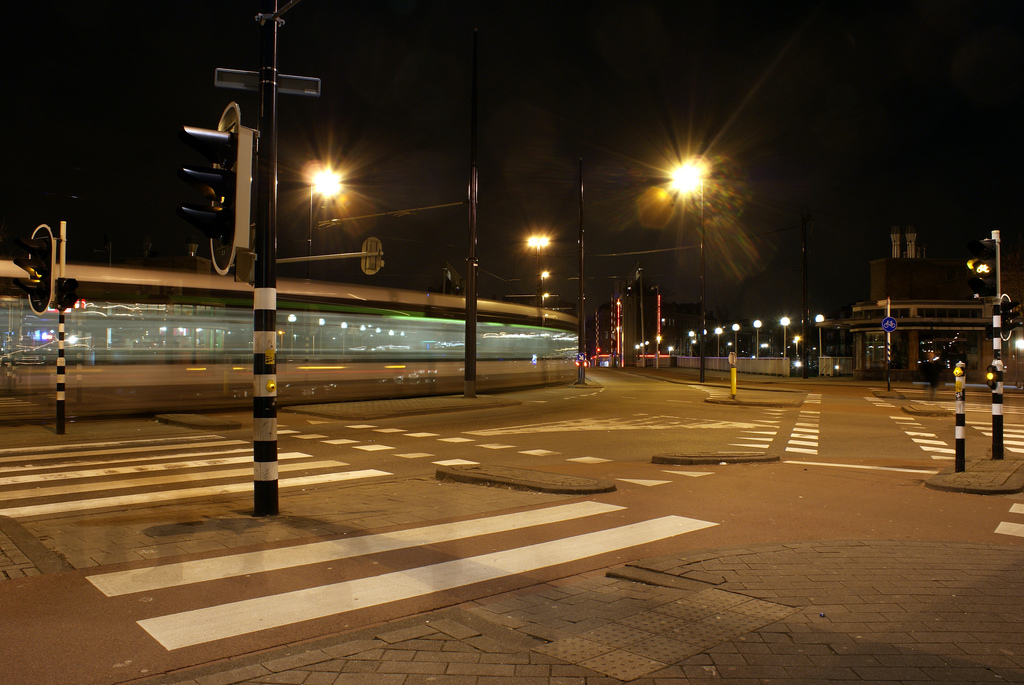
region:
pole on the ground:
[51, 379, 72, 430]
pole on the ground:
[443, 350, 489, 405]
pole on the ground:
[712, 358, 750, 401]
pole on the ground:
[599, 335, 628, 362]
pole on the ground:
[984, 414, 998, 463]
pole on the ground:
[705, 356, 747, 398]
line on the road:
[554, 524, 665, 579]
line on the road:
[332, 508, 419, 547]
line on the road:
[43, 502, 89, 528]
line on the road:
[165, 433, 186, 438]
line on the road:
[416, 452, 474, 481]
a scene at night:
[32, 47, 1003, 598]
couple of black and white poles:
[13, 64, 350, 548]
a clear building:
[9, 209, 598, 454]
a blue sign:
[863, 304, 908, 336]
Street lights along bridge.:
[672, 308, 840, 344]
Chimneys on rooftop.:
[879, 219, 930, 258]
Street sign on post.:
[207, 62, 328, 101]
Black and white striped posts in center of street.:
[939, 224, 1022, 472]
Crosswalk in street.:
[0, 422, 725, 656]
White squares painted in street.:
[276, 409, 539, 466]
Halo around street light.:
[602, 86, 771, 274]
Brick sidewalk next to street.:
[263, 543, 1022, 681]